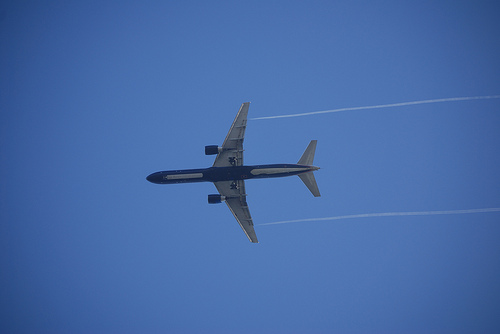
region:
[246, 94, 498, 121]
Smoke trailing behind the airplane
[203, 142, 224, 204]
Engines on the airplane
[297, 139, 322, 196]
The tail of the airplane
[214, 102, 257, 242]
The wings of the airplane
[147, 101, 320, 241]
An airplane in the sky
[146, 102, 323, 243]
The airplane is flying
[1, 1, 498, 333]
The sky above the airplane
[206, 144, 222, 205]
The airplane has two engines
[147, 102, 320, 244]
The airplane is trailing smoke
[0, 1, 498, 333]
A clear sky around the airplane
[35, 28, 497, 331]
An overhead jet plane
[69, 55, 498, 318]
a jet plane with its streamer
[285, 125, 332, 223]
tail of a jet plane from underneath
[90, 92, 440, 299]
a plane in the sky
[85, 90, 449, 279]
a jet plane in the sky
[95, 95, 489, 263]
a jet plane from underneath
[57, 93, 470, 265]
a jet airplane from underneath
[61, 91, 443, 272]
a jet plane with two engines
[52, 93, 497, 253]
a two engine plane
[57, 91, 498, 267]
a two-engine jet airplane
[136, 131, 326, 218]
the plane is in air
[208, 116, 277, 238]
the wings are white in color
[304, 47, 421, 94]
the sky is claer blue in color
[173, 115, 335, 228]
plane is moving horizontaly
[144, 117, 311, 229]
the plane is in motion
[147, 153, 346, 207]
the plane inner part is dark blue in color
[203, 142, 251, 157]
the exhauster are blue in color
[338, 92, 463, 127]
the plane emits smoke as it moves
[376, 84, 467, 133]
the smoke is white in color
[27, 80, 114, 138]
part of the clear sky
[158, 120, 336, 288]
plane is in motion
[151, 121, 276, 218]
plane is blu in color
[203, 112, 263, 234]
wings are white incolor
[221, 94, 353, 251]
plane emits smoke as it moves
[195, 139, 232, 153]
exhauster are blue incolor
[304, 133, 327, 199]
tail is whitin colro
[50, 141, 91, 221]
sky is clear blue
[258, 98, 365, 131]
smoke is white in color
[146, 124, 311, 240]
plane is in air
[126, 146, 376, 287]
plane is moving horizontaly